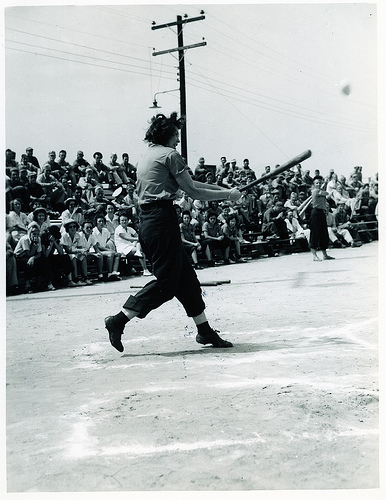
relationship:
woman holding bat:
[104, 117, 241, 352] [238, 150, 311, 191]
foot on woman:
[99, 314, 138, 354] [104, 117, 241, 352]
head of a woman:
[119, 108, 187, 144] [85, 119, 286, 361]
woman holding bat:
[298, 173, 346, 272] [226, 145, 314, 193]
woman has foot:
[104, 112, 241, 352] [173, 284, 239, 359]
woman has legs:
[104, 117, 241, 352] [103, 237, 234, 357]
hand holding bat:
[167, 154, 254, 227] [224, 116, 329, 208]